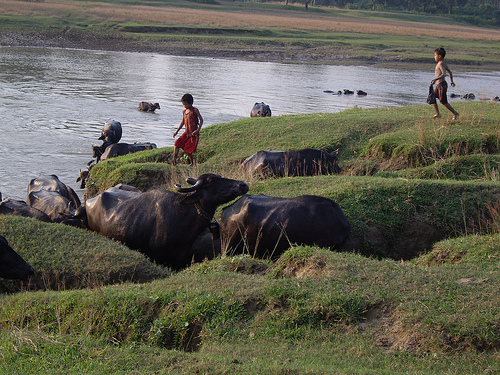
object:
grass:
[0, 100, 500, 375]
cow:
[242, 147, 341, 180]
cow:
[357, 90, 367, 96]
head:
[174, 173, 250, 207]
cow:
[84, 173, 352, 273]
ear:
[174, 190, 202, 207]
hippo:
[221, 193, 352, 263]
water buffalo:
[26, 175, 81, 222]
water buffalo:
[98, 119, 122, 143]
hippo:
[0, 174, 83, 229]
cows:
[450, 93, 500, 101]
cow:
[250, 102, 271, 117]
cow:
[139, 101, 160, 112]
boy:
[427, 48, 460, 120]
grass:
[0, 12, 499, 65]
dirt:
[184, 35, 314, 63]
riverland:
[1, 1, 500, 73]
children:
[172, 48, 460, 165]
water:
[0, 46, 500, 203]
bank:
[0, 29, 497, 72]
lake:
[0, 40, 500, 203]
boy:
[168, 93, 203, 165]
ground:
[0, 0, 500, 375]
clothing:
[174, 105, 199, 154]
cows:
[324, 89, 367, 96]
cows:
[76, 169, 89, 189]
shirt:
[426, 85, 435, 105]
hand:
[431, 79, 436, 84]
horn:
[174, 177, 204, 192]